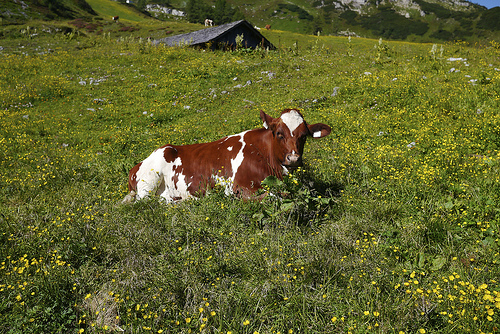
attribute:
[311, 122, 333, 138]
ear — brown, white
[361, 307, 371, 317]
flower — little, yellow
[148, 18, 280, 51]
roof — rustic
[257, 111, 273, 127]
ear — white, brown